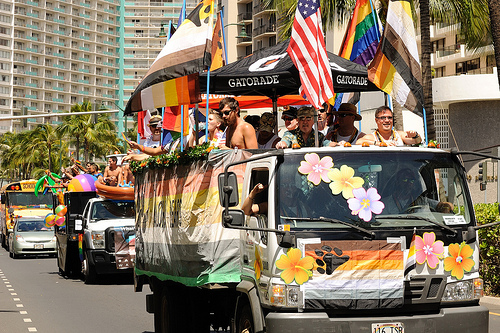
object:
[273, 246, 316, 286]
flower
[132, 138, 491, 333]
truck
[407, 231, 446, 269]
flower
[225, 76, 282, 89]
writing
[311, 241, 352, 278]
paw print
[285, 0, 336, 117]
flag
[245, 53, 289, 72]
symbol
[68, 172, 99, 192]
ball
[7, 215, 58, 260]
car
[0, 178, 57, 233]
school bus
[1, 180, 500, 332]
street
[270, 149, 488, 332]
front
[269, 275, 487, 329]
grill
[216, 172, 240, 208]
mirrors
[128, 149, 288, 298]
side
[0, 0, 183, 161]
complex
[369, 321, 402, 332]
license plate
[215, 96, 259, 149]
man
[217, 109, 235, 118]
glasses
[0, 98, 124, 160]
cluster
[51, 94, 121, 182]
trees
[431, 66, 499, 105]
balcony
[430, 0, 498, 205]
building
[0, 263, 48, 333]
lines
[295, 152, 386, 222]
flowers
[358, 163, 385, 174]
mirror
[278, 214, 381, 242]
wiper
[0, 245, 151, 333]
road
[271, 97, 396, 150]
people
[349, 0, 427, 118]
flags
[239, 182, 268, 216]
arm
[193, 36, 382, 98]
tent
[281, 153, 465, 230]
windshield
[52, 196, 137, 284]
cars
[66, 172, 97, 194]
beach ball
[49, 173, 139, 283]
truck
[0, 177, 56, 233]
bus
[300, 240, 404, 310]
banner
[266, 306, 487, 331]
bumper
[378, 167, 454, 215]
man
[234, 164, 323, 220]
passenger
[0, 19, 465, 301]
parade